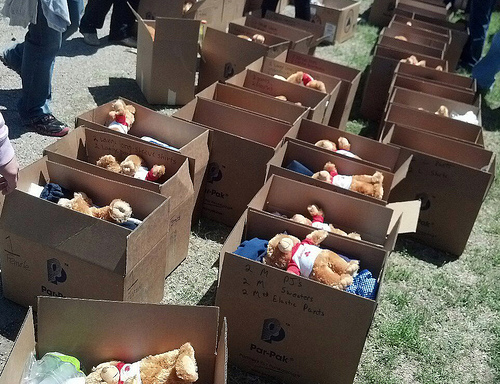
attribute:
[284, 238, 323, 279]
shirt — red, white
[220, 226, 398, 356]
box — open, cardboard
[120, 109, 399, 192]
boxes — cardboard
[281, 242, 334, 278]
shirt — red, white